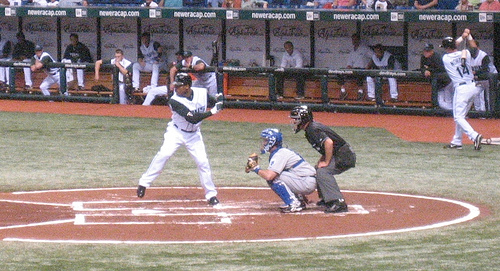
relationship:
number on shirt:
[454, 62, 468, 77] [440, 48, 485, 85]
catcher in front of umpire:
[243, 128, 320, 216] [293, 106, 355, 215]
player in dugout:
[29, 44, 69, 92] [2, 13, 499, 112]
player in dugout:
[95, 48, 135, 101] [2, 13, 499, 112]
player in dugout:
[132, 31, 162, 93] [2, 13, 499, 112]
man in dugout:
[273, 37, 312, 101] [2, 13, 499, 112]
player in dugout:
[364, 41, 404, 104] [2, 13, 499, 112]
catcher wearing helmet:
[240, 123, 320, 216] [259, 126, 284, 151]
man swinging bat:
[131, 72, 224, 206] [208, 34, 224, 96]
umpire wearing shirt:
[293, 106, 355, 215] [299, 120, 345, 158]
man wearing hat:
[131, 72, 224, 206] [171, 68, 194, 88]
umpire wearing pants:
[293, 106, 355, 215] [315, 148, 355, 202]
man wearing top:
[131, 72, 224, 206] [164, 88, 213, 122]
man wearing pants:
[131, 72, 224, 206] [134, 120, 218, 202]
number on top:
[454, 62, 468, 77] [441, 49, 491, 84]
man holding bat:
[131, 72, 224, 206] [193, 42, 233, 139]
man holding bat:
[131, 72, 224, 206] [202, 59, 229, 113]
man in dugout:
[131, 72, 224, 206] [16, 148, 478, 247]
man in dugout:
[131, 72, 224, 206] [17, 150, 481, 267]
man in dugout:
[273, 37, 312, 101] [40, 41, 465, 135]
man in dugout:
[273, 24, 325, 122] [35, 26, 441, 143]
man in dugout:
[349, 28, 429, 183] [76, 18, 414, 114]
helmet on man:
[281, 100, 331, 140] [277, 84, 391, 252]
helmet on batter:
[156, 32, 222, 102] [122, 44, 275, 253]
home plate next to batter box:
[131, 206, 166, 218] [74, 212, 231, 226]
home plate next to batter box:
[131, 206, 166, 218] [72, 198, 224, 215]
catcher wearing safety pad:
[243, 128, 320, 216] [270, 179, 291, 208]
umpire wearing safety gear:
[293, 106, 355, 215] [286, 102, 312, 135]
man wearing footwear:
[131, 72, 224, 206] [207, 194, 219, 206]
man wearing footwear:
[131, 72, 224, 206] [135, 185, 147, 200]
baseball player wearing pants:
[137, 70, 225, 201] [134, 120, 218, 202]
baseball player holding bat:
[137, 70, 225, 201] [211, 39, 222, 98]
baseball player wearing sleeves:
[137, 70, 225, 201] [168, 93, 220, 123]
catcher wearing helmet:
[243, 128, 320, 216] [259, 127, 280, 153]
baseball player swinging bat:
[137, 70, 225, 201] [210, 37, 226, 99]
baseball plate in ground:
[128, 205, 167, 219] [3, 96, 497, 267]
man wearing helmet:
[131, 72, 224, 206] [170, 72, 191, 86]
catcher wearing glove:
[243, 128, 320, 216] [245, 154, 261, 174]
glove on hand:
[245, 154, 261, 174] [250, 159, 257, 168]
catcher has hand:
[243, 128, 320, 216] [250, 159, 257, 168]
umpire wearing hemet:
[293, 106, 355, 215] [291, 106, 315, 135]